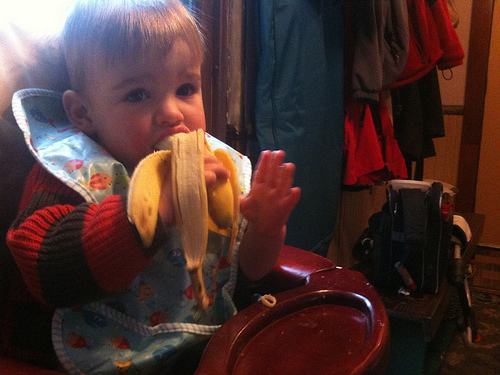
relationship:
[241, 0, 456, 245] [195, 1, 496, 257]
coats hanging on wall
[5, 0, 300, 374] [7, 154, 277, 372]
baby wearing sweater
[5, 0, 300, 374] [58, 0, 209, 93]
baby has blonde hair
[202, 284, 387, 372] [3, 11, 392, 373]
tray on highchair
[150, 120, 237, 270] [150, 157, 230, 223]
banana in hand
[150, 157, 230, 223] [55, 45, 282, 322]
hand of child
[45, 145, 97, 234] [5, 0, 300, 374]
sweater on baby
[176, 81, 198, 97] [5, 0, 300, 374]
eye of baby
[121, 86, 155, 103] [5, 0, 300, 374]
eye of baby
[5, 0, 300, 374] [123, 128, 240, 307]
baby eating banana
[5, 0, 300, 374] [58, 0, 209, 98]
baby has blonde hair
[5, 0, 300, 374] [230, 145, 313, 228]
baby has hand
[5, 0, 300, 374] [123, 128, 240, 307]
baby has banana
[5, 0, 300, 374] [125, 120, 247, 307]
baby eating banana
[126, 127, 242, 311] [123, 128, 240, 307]
banana peel of banana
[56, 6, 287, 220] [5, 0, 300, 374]
head of baby